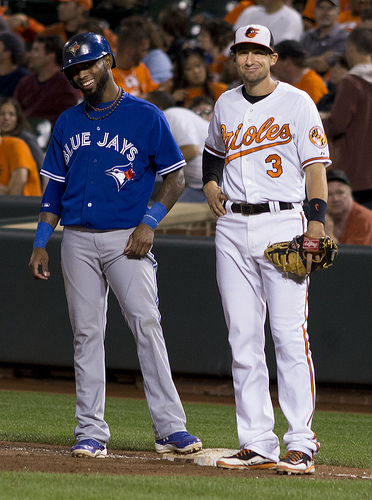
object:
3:
[265, 154, 283, 182]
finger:
[305, 251, 314, 273]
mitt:
[265, 235, 306, 283]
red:
[302, 239, 320, 251]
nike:
[311, 200, 321, 214]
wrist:
[308, 221, 322, 229]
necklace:
[84, 84, 122, 124]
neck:
[83, 68, 117, 103]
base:
[193, 441, 217, 471]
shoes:
[273, 448, 317, 476]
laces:
[287, 452, 301, 462]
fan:
[323, 165, 371, 245]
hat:
[325, 167, 349, 186]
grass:
[0, 390, 367, 486]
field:
[0, 377, 372, 496]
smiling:
[80, 77, 101, 91]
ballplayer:
[30, 28, 203, 457]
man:
[332, 27, 372, 175]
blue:
[93, 40, 105, 57]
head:
[58, 31, 113, 99]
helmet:
[60, 32, 112, 73]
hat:
[230, 21, 272, 50]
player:
[201, 20, 328, 468]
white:
[286, 348, 299, 394]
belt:
[219, 202, 295, 211]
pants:
[215, 197, 320, 450]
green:
[324, 426, 360, 453]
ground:
[0, 441, 370, 478]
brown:
[19, 145, 31, 162]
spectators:
[176, 41, 232, 108]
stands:
[0, 0, 372, 248]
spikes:
[278, 470, 308, 478]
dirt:
[184, 466, 220, 474]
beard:
[72, 76, 107, 101]